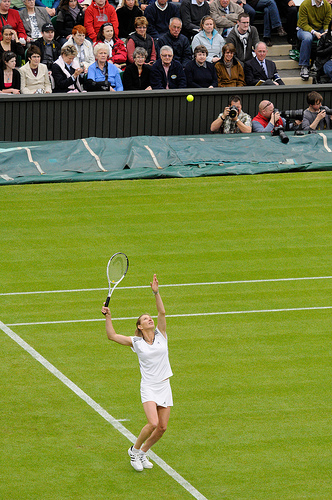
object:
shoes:
[127, 445, 143, 472]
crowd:
[0, 0, 332, 93]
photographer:
[209, 95, 252, 134]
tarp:
[0, 129, 332, 182]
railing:
[0, 85, 331, 140]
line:
[0, 267, 332, 298]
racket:
[101, 250, 130, 316]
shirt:
[86, 61, 124, 92]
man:
[243, 41, 285, 87]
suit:
[244, 58, 279, 88]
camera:
[227, 106, 239, 119]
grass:
[0, 169, 332, 499]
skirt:
[139, 376, 173, 409]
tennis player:
[103, 272, 176, 474]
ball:
[185, 93, 194, 103]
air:
[0, 0, 331, 495]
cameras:
[271, 122, 289, 144]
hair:
[71, 25, 87, 35]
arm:
[85, 67, 110, 92]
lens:
[229, 110, 237, 118]